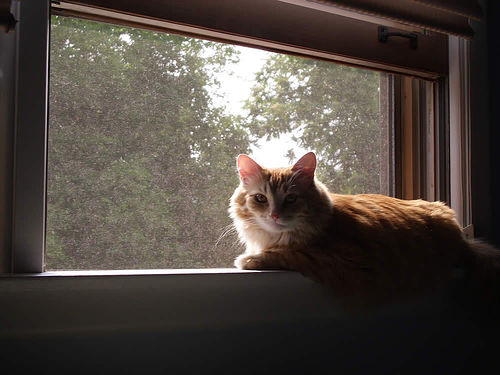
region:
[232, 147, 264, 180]
The left ear of the cat.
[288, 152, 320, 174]
The right ear of the cat.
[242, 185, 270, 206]
The left eye of the cat.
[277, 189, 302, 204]
The right eye of the cat.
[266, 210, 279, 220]
The small pink nose of the cat.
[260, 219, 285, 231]
The mouth area of the cat.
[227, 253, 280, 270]
The front paws of the cat on the windowsill.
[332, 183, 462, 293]
The body of the cat.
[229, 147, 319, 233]
The head of the cat on the window sill.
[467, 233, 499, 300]
The tail of the cat.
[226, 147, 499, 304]
orange and white cat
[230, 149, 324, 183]
pink cat ears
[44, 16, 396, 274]
trees out the window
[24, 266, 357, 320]
white window sill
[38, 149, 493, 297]
cat sitting on the window sill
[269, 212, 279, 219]
little pink cat nose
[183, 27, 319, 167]
bright clear sky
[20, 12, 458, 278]
wide window is open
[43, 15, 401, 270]
mesh screen in the window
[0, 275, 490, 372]
white wall is not lit up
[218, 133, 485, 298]
Orange tabby cat.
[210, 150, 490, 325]
Cat sitting on a windowsill.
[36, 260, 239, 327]
White windowsill.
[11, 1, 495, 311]
Window with a cat sitting in it.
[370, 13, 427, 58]
Metal handle used to open the window.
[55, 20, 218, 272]
large tree full with leaves growing outside the window.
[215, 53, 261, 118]
Clear sky outside the building.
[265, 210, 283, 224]
Pink nose on the cat.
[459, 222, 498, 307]
Bushy tail hanging down.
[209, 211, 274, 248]
Long white whiskers of the cat.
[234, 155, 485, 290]
cat is red and white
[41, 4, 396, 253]
cat is sitting at window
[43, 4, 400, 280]
light shining through window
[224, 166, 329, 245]
cat's face is furry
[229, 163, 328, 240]
cat is awake and alert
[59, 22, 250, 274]
trees outside screen window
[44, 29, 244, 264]
trees are leafy and green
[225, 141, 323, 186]
cat has light pink ears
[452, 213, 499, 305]
cat's tail is barely visible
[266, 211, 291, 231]
cat has small nose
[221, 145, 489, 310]
the cat is lying down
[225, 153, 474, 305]
the cat is looking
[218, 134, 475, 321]
the cat is on window seel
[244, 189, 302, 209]
the cat has eyes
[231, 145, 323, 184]
the cat has ears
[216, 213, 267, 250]
the cat has wiskers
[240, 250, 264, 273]
the cat has a front paw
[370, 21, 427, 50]
the handle is brown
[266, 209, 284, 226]
the cat has a pink nose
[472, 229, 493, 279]
the cat has a tail